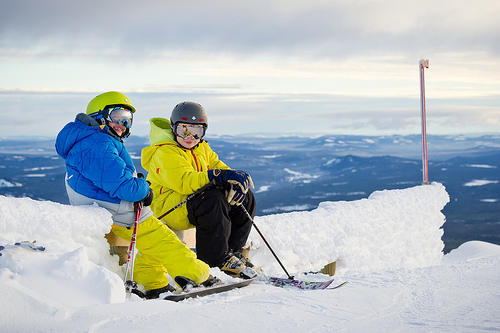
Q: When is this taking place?
A: Daytime.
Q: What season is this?
A: Winter.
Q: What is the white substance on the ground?
A: Snow.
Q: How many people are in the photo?
A: Two.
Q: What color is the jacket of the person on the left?
A: Blue.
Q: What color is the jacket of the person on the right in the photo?
A: Yellow.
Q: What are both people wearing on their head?
A: Helmets.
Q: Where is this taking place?
A: On snow.